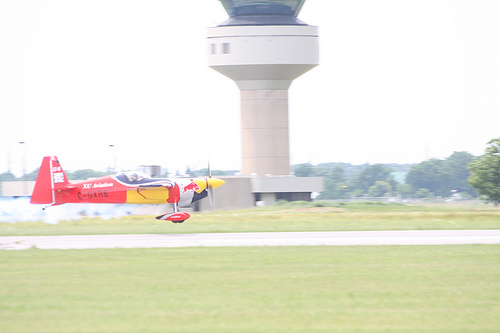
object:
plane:
[30, 155, 225, 223]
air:
[3, 4, 499, 225]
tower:
[203, 1, 325, 205]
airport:
[0, 139, 499, 332]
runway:
[1, 231, 499, 251]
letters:
[77, 192, 109, 200]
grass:
[1, 252, 497, 266]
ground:
[247, 210, 499, 220]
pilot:
[130, 173, 137, 183]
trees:
[331, 138, 499, 204]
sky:
[0, 0, 192, 73]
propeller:
[205, 160, 223, 204]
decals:
[53, 175, 115, 200]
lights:
[17, 142, 117, 199]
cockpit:
[117, 171, 152, 185]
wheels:
[171, 219, 184, 224]